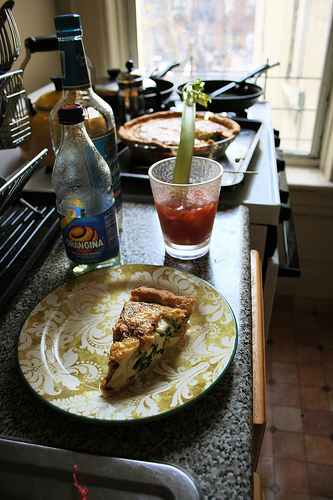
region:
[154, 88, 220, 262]
a glass filled with red liquid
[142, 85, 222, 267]
a bloody Mary cocktail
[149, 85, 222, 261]
a cup with a stick of celery in it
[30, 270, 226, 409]
a plate of pie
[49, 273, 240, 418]
a plate has an ornate pattern and a slice of pie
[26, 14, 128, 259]
a couple of bottles on a countertop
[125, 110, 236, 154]
a pie sits on the top of an oven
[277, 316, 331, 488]
the kitchen floor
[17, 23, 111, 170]
a yellow cooking kettle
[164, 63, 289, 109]
black frying pan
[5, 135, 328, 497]
Kitchen counter with food and drinks on top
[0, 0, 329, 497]
Kitchen counter and stove with food on top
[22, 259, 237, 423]
Flower plate with a slice of pie inside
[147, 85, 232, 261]
Tomato juice with a celery stick inside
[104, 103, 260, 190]
A pie on top of the cookie sheet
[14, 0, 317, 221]
Kitchen stove with food on top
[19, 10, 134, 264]
Empty glass, juice bottles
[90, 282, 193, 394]
A piece of pie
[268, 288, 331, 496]
Different shades of brown tiled floor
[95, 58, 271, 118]
Empty pots on top of the stove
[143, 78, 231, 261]
A Bloody Mary.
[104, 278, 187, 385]
A piece of quiche.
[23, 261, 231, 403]
A green plate with a floral design on it.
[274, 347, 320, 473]
The flooring is made up of brown tiles.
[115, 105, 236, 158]
A quiche.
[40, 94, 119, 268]
An empty glass bottle of soda.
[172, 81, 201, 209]
A stalk of celery in the drink.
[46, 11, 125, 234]
A bottle of alcohol.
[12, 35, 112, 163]
A yellow tea kettle behind the two glass bottles.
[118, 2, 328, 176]
A large window next to the stove.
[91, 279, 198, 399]
the food is on the plate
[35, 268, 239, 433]
the plate is on the counter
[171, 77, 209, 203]
celery stalk is on the counter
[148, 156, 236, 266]
the glass has salsa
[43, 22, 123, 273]
bottles are on the counter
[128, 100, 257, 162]
the pie is on a tray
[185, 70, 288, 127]
the pans are on the stove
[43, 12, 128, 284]
two bottles on the counter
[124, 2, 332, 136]
the curtains is open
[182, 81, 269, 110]
the pan is black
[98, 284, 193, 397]
Slice of quiche lorraine.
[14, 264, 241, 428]
Green and white paisley plate.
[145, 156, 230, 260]
Bloody Mary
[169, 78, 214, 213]
Stalk of celery.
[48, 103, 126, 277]
Empty orangeina bottle.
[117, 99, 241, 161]
Fresh baked quiche in pie pan.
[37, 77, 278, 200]
Crowded white stove top.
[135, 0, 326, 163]
Large uncurtained kitchen window.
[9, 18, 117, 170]
Old fashioned yellow teapot.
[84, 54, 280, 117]
Two nonstick metal frying pans.